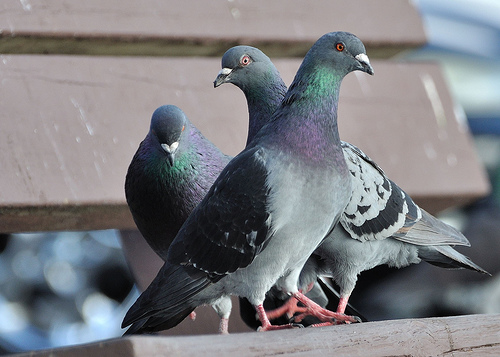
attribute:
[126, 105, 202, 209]
pigeon — looking evil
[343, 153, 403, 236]
feathers — gray and black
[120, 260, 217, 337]
tailfethers — long, black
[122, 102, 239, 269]
pigeon — blue , green, purple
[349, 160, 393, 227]
markings — white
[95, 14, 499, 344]
pigeons — three, park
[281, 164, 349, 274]
belly — grey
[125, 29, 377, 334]
pigeon — green and purple, green, purple, Black, tan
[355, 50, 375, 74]
beak — black, white tops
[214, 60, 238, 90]
beak — black, white tops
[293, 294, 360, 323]
feet — pink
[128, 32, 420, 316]
pigeons — three, standing together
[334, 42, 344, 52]
eye — pigeon's, orange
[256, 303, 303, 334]
feet — reddish orange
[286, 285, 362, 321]
feet — reddish orange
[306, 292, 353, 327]
feet — reddish orange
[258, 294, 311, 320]
feet — reddish orange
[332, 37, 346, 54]
pigeon's eye — orange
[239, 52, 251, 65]
pigeon's eye — orange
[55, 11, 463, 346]
bench — park bench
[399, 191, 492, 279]
tail feathers — long, gray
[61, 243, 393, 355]
bench — park bench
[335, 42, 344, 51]
eye — brown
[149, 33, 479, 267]
bench — cracked wood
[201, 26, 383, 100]
heads — opposite way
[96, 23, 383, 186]
heads — pigeon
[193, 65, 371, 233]
pigeon — park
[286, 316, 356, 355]
bench — wooden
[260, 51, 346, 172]
neck — green and purple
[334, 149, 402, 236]
stripes — black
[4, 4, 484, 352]
bench — wooden, wood, dark brown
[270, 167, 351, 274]
feathers — light gray